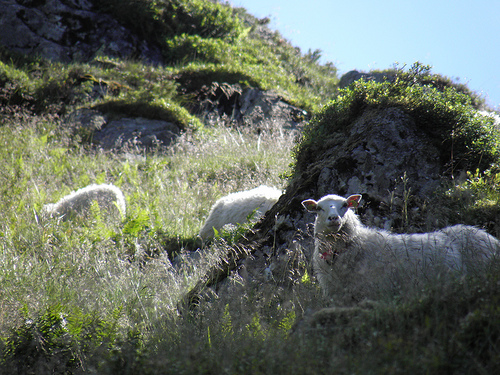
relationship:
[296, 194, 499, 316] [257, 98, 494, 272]
lamb by rock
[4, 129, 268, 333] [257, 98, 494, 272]
grass by rock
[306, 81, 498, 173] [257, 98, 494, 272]
grass on rock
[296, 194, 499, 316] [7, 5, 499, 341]
lamb on a hill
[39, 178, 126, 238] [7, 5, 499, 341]
lamb on a hill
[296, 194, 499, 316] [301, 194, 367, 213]
lamb has ears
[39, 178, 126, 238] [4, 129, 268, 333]
lamb in grass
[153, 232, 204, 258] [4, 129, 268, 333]
shadow on grass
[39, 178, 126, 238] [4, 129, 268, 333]
lamb eating grass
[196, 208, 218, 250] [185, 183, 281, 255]
neck of a lamb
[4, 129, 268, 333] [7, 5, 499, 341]
grass on hill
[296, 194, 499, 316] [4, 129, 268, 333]
lamb in grass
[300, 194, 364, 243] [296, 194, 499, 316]
head of lamb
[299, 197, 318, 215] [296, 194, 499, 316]
left ear of lamb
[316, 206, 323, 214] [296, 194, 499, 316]
left eye of sheep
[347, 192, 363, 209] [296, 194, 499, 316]
right ear of lamb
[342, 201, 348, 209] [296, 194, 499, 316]
right eye of lamb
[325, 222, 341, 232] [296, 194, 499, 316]
mouth of lamb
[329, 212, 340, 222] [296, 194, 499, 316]
nose of lamb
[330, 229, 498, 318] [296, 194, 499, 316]
body of lamb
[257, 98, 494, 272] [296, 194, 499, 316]
rock behind lamb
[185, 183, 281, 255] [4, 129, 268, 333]
lamb eating grass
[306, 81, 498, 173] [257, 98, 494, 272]
grass on a rock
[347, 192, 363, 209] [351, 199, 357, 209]
right ear has tag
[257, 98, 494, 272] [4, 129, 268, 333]
rock in grass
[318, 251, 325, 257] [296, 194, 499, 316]
red on lamb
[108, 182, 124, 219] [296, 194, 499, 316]
butt of lamb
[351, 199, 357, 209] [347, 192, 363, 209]
tag in right ear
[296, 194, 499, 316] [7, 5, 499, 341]
lamb on hill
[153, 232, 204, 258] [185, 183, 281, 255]
shadow from lamb